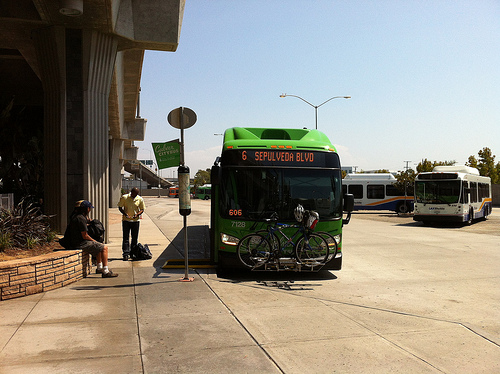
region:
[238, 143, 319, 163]
led screen on the front of the bus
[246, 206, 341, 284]
bikes on front of the bus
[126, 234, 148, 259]
bag laying on the ground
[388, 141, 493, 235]
bus parked off to the side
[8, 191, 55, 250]
plant growing by the building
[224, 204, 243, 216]
bus number in the window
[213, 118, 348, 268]
the bus is green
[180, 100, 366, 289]
the bus is green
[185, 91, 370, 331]
the bus is green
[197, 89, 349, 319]
the bus is green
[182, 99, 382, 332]
the bus is green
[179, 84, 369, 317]
the bus is green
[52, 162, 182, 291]
people at the bus stop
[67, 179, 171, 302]
people at the bus stop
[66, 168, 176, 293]
people at the bus stop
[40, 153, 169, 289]
people at the bus stop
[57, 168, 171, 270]
people at the bus stop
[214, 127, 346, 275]
the bus is at the bus stop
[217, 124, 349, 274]
the bus is green in color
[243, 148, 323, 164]
the bus has a lighted sign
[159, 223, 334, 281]
a shadow is on the ground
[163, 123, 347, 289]
the bus is casting a shadow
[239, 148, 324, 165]
the bus has a lighted sign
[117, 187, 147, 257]
a person is standing at the stop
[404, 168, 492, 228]
a bus is in the background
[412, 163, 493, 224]
the bus is white in color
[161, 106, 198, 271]
a sign is at the stop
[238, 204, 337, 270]
Bicycles on the front of the bus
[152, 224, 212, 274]
A shadow on the ground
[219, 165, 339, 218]
Windows on the bus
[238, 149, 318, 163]
An electronic display on the bus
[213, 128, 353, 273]
A green bus at a stop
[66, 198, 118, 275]
A man sitting near a bus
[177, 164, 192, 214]
A map of the bus route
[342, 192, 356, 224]
A mirror on the bus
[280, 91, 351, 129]
A lamp post behind the bus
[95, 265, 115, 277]
The man is wearing shoes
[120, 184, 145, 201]
head of a person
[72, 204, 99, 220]
head of a person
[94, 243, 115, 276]
leg of a person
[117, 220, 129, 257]
leg of a person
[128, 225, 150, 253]
leg of a person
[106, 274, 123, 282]
feet of a person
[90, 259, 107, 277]
feet of a person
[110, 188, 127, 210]
arm of a person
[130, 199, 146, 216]
arm of a person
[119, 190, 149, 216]
body of a person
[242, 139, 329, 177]
the sign is orange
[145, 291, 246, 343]
the street is brown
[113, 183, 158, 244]
man is black and standing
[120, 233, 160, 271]
bags are black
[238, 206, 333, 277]
the bikes on the bus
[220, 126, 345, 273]
the bus is green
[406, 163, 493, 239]
the bus is parked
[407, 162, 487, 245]
the bus on the road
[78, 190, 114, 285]
the person is sitting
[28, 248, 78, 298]
the wall is stone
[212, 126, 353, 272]
the bikes at the front of the bus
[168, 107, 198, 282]
the sign on the pole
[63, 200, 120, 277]
the man is sitting down